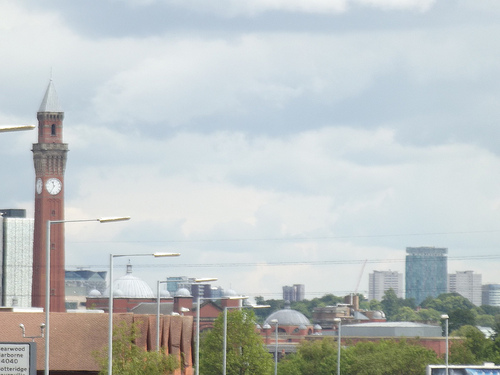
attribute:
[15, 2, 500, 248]
sky — grey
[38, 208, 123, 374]
post — tall, white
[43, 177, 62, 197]
clock — white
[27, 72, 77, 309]
tower — red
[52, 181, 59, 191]
hands — black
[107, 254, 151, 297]
roof — white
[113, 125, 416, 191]
clouds — big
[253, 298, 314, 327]
building — grey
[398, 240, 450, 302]
building — tall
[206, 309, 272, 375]
trees — green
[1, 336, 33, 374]
sign — black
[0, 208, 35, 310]
building — white